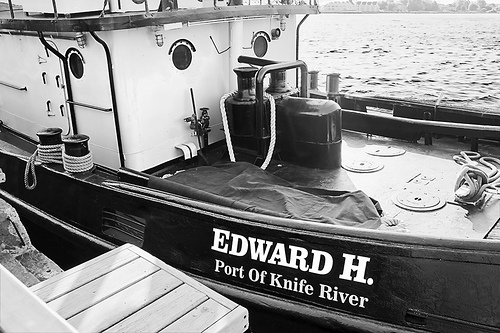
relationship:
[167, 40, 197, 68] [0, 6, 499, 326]
portal in a boat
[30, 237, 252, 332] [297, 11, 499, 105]
stone going down to river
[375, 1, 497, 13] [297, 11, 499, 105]
trees across from river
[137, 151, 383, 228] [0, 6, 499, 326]
tarp on boat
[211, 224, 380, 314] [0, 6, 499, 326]
name painted on boat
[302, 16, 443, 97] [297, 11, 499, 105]
sunlight on river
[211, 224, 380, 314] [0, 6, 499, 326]
name on boat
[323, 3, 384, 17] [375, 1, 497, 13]
boat near trees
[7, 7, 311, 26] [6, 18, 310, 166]
roof on cabin